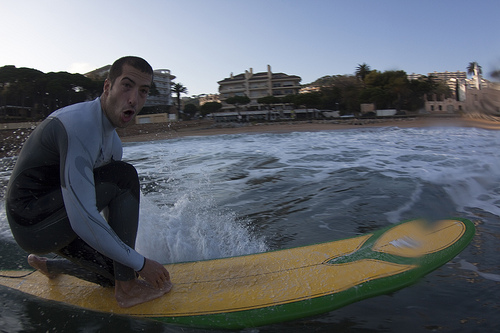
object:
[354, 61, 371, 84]
palm tree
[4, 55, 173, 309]
man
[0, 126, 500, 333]
ocean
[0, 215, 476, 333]
surfboard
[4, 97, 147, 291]
wetsuit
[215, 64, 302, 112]
building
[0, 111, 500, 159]
beach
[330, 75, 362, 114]
trees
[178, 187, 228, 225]
bubbles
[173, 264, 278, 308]
water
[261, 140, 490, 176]
foam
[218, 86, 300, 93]
levels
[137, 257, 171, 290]
hand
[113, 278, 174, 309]
foot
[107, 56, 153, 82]
hair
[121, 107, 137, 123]
mouth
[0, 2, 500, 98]
sky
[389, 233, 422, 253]
sticker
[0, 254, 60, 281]
cord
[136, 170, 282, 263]
splashing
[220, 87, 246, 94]
balcony